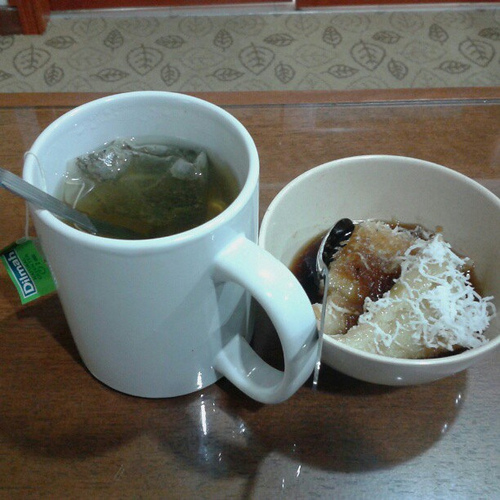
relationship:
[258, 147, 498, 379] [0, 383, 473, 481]
bowl casting shadow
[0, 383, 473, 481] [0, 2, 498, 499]
shadow on table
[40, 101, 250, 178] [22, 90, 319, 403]
condensation on side of cup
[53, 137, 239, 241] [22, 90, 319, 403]
green tea inside cup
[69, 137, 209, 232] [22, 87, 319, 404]
tea bag inside cup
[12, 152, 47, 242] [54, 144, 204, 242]
thread of teabag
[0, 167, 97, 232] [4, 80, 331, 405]
spoon in cup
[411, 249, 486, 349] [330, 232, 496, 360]
cheese on coconut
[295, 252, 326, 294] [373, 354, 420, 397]
coffee of bowl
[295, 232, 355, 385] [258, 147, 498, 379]
teaspoon on bowl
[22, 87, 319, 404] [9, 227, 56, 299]
cup behind bag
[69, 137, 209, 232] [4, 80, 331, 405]
tea bag in cup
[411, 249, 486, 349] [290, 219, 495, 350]
cheese on food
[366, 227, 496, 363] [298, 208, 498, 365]
coconut on food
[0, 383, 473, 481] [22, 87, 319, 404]
shadow of cup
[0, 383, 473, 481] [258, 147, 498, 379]
shadow of bowl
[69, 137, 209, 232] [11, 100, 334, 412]
tea bag in cup